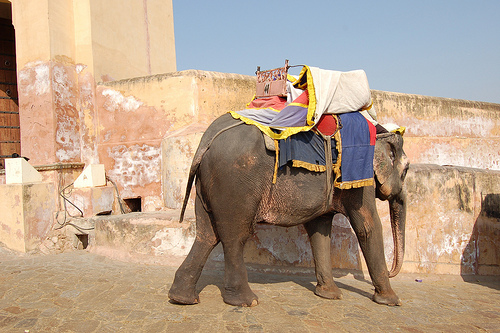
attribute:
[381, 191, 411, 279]
trunk — long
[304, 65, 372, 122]
cloth — yellow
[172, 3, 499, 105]
sky — blue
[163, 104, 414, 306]
elephant — large, tail, adult